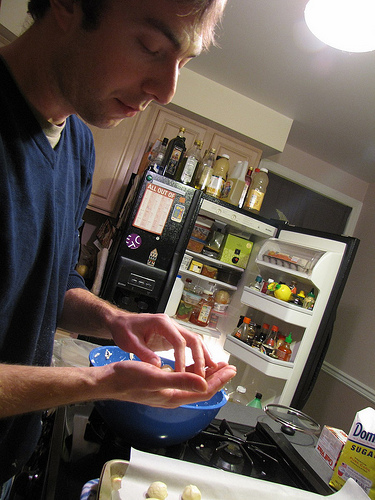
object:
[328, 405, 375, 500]
bag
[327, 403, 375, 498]
sugar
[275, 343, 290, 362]
sauce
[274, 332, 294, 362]
bottle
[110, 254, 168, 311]
ice dispencer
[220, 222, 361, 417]
door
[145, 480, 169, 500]
ball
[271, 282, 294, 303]
ball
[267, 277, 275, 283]
top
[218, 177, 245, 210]
oil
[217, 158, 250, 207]
bottle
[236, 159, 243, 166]
top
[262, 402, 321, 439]
pot top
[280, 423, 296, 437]
knob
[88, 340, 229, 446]
bowl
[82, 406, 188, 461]
burner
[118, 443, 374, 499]
paper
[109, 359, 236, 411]
hand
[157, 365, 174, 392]
dough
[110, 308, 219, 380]
hand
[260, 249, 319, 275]
carton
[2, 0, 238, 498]
man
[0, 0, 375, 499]
kitchen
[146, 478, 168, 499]
cookies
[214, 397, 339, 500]
counter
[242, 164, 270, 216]
bottle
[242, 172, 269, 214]
juice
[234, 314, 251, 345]
bottle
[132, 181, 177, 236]
magnets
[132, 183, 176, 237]
paper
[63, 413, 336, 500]
stove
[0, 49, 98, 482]
t-shirt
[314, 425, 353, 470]
box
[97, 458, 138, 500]
cookie sheet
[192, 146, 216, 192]
bottle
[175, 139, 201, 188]
bottles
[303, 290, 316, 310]
container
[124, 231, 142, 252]
magnet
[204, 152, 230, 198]
container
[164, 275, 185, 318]
milk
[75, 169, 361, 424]
frigerator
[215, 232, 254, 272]
box